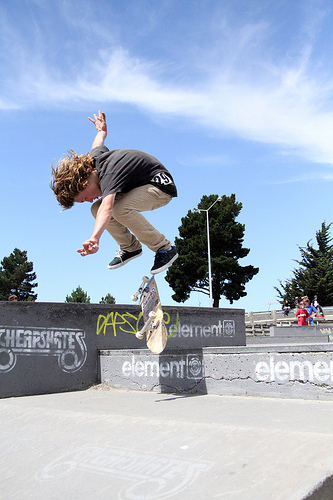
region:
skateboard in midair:
[132, 273, 169, 357]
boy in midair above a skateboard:
[49, 110, 179, 272]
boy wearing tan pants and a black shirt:
[51, 110, 185, 272]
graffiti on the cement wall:
[95, 310, 144, 339]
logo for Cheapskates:
[1, 327, 89, 370]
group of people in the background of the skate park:
[296, 293, 318, 325]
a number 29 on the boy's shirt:
[154, 171, 171, 187]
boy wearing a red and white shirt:
[295, 302, 308, 322]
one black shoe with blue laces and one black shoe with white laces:
[106, 245, 176, 272]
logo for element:
[122, 356, 203, 379]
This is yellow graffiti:
[46, 310, 197, 346]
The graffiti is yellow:
[82, 294, 216, 389]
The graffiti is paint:
[83, 296, 171, 380]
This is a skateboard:
[134, 282, 177, 390]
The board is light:
[99, 279, 196, 380]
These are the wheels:
[115, 282, 167, 366]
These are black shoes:
[76, 241, 179, 284]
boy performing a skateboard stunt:
[50, 115, 178, 271]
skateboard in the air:
[130, 271, 170, 353]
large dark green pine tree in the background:
[166, 194, 255, 305]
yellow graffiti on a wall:
[94, 310, 143, 340]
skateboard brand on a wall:
[120, 355, 208, 380]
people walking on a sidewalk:
[295, 296, 320, 329]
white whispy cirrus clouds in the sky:
[1, 6, 329, 171]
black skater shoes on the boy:
[107, 245, 180, 275]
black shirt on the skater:
[80, 143, 184, 199]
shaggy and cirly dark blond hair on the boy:
[52, 149, 91, 207]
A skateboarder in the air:
[47, 107, 185, 281]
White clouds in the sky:
[1, 1, 331, 200]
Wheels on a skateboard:
[129, 273, 159, 344]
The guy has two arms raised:
[48, 106, 121, 263]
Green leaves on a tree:
[166, 190, 264, 308]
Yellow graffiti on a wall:
[91, 307, 172, 338]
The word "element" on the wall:
[117, 353, 188, 383]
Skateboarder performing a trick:
[45, 106, 189, 360]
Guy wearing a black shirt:
[50, 140, 181, 198]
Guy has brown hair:
[41, 148, 105, 215]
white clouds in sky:
[1, 0, 331, 300]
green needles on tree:
[280, 221, 332, 304]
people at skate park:
[293, 295, 323, 326]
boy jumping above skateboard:
[51, 110, 180, 353]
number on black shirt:
[90, 145, 178, 197]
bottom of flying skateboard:
[141, 275, 166, 352]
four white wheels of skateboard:
[130, 276, 155, 339]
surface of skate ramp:
[0, 390, 332, 498]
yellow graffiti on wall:
[94, 307, 180, 339]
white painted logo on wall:
[0, 324, 88, 373]